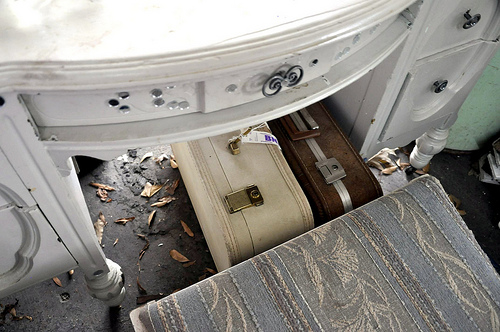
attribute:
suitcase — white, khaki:
[191, 146, 302, 228]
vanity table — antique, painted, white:
[14, 11, 462, 121]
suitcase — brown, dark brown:
[299, 121, 356, 200]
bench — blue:
[228, 248, 493, 329]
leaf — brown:
[171, 248, 191, 264]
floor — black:
[123, 242, 136, 268]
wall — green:
[471, 78, 497, 153]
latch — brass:
[228, 189, 259, 204]